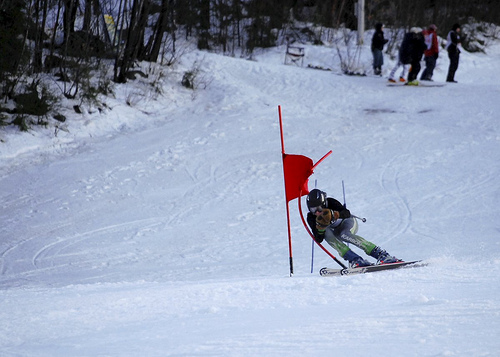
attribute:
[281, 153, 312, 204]
flag — red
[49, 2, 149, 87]
trunks — brown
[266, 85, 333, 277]
pole — red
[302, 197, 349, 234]
coat — black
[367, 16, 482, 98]
people — standing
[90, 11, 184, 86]
trees — bare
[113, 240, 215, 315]
snow — white